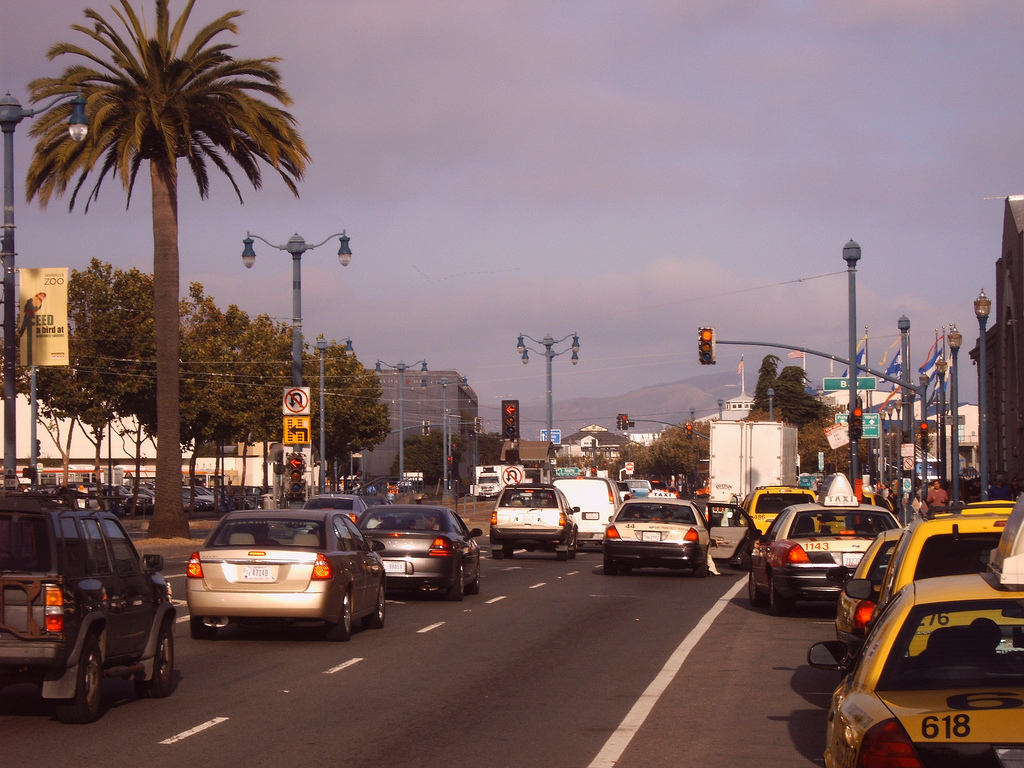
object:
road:
[2, 482, 850, 766]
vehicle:
[597, 493, 703, 556]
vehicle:
[485, 479, 564, 532]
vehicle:
[373, 510, 480, 590]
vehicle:
[180, 505, 375, 635]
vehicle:
[2, 493, 185, 707]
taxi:
[829, 549, 1024, 766]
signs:
[277, 376, 316, 476]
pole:
[287, 230, 309, 522]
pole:
[722, 333, 905, 389]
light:
[688, 323, 715, 367]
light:
[498, 392, 530, 448]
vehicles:
[487, 448, 725, 559]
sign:
[547, 454, 610, 487]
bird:
[14, 275, 58, 368]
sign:
[2, 269, 81, 391]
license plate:
[210, 549, 298, 593]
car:
[180, 493, 397, 634]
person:
[900, 467, 954, 532]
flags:
[898, 312, 966, 420]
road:
[2, 528, 886, 762]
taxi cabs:
[718, 476, 1019, 764]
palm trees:
[2, 1, 405, 578]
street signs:
[263, 372, 328, 500]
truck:
[699, 418, 806, 516]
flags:
[813, 351, 963, 436]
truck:
[462, 455, 555, 508]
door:
[692, 513, 755, 565]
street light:
[488, 380, 527, 473]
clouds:
[6, 14, 1021, 462]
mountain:
[435, 359, 793, 467]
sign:
[263, 418, 321, 474]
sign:
[265, 377, 330, 485]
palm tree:
[2, 1, 309, 558]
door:
[699, 500, 768, 574]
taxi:
[591, 500, 760, 593]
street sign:
[799, 354, 895, 445]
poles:
[816, 237, 870, 492]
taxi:
[584, 476, 760, 587]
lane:
[181, 532, 765, 764]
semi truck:
[703, 405, 812, 537]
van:
[550, 467, 619, 556]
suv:
[477, 466, 586, 566]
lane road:
[2, 545, 717, 759]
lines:
[151, 565, 750, 760]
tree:
[72, 26, 228, 186]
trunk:
[126, 191, 224, 583]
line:
[599, 605, 701, 729]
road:
[384, 573, 562, 707]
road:
[295, 677, 475, 736]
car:
[57, 536, 133, 655]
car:
[350, 484, 526, 627]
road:
[458, 586, 606, 716]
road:
[465, 586, 745, 720]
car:
[473, 437, 599, 576]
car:
[608, 469, 742, 577]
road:
[441, 547, 740, 707]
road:
[551, 601, 737, 720]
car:
[413, 441, 571, 552]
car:
[173, 467, 256, 534]